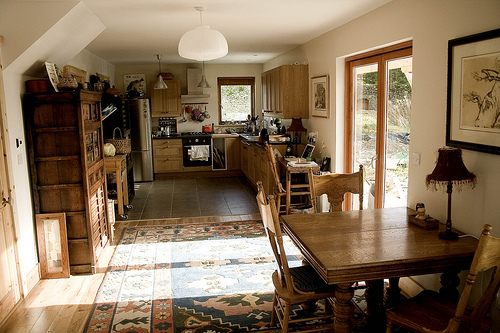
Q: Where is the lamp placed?
A: Table.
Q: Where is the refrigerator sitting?
A: Kitchen.